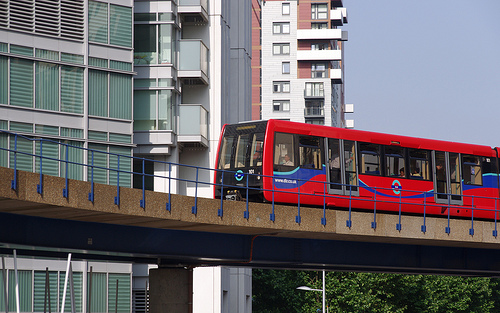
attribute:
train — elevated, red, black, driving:
[211, 120, 498, 225]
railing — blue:
[1, 130, 499, 238]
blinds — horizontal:
[62, 3, 88, 44]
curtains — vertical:
[37, 48, 61, 112]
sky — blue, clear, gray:
[341, 0, 498, 150]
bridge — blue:
[0, 125, 500, 280]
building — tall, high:
[1, 1, 134, 188]